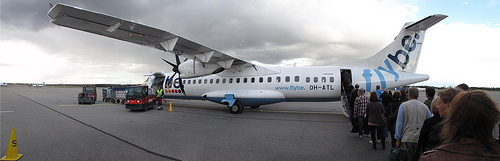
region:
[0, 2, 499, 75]
a sky with dark clouds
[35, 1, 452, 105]
a white airplane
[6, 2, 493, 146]
an airplane on a tarmac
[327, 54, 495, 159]
a group of people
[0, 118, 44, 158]
a yellow cone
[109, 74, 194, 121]
a red truck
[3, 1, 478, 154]
a scene outside here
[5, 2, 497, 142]
a scene during the day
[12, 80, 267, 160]
gray pavement here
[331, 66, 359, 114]
an open door here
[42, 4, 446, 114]
the airplane is white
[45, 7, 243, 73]
the airplane has a large wing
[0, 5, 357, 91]
large white clouds in the sky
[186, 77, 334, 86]
the airplane has many windows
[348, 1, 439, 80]
the airplane's tail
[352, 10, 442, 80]
light and dark blue lettering on the tail of the plane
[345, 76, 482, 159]
line of people waiting to board the plane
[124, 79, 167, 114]
luggage truck servicing the plane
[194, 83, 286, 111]
the airplane's engine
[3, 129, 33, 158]
a yellow cone on the pavement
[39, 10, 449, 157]
a nice looking airport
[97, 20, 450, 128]
a plane about to take off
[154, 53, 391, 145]
a white airplane in background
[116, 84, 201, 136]
a red vehicle in background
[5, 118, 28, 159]
a yellow cone in airport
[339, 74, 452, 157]
passengers boarding the airplane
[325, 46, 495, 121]
blue design on airplane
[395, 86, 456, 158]
man wearing blue sleeves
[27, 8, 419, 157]
grey clouds in background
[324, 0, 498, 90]
clear blue sky in background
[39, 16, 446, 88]
flybe. plane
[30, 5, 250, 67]
the wing of the airplane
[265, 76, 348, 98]
Ohio to Atlanta flight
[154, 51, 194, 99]
the propeller of the airplane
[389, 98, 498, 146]
people boarding the airplane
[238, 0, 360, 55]
the clouds in the sky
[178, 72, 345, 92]
the windows on the airplane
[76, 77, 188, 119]
the luggage thing that is going to the plane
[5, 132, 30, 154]
the yellow cone in the photo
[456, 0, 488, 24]
a little bit of blue sky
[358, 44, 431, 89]
the words fly be on the side of a plane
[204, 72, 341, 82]
a line of windows on the side of a plane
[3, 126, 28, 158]
a yellow safety cone on a runway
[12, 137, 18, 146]
the letter S on a safety cone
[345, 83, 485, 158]
a group of people boarding a plane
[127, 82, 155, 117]
a red vehicle on the runway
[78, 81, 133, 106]
a set of vehicles to the left of the plane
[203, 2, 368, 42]
dark clouds in the sky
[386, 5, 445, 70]
the white tail fin of the plane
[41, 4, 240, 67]
the long white wing of the plane